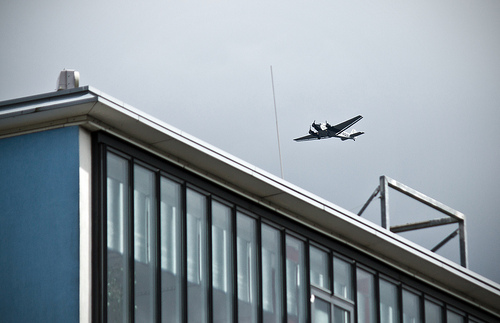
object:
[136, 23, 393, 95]
clouds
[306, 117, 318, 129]
propeller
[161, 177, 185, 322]
window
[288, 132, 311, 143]
wing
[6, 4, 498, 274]
cloud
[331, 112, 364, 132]
wing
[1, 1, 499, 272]
sky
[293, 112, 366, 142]
plane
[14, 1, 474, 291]
sky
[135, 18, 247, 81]
clouds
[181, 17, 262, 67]
clouds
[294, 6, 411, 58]
sky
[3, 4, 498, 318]
photo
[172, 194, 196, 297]
window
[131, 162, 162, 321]
window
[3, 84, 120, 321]
wall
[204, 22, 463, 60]
sky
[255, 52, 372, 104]
clouds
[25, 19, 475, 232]
sky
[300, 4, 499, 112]
clouds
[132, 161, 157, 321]
windows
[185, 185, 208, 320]
windows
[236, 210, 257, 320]
windows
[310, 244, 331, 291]
windows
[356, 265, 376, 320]
windows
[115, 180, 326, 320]
building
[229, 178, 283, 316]
window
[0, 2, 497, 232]
sky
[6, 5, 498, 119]
sky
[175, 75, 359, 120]
air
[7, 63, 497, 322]
building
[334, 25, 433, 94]
clouds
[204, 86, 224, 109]
bad sentence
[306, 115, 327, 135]
front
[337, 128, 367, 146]
back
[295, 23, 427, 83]
clouds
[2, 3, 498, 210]
sky